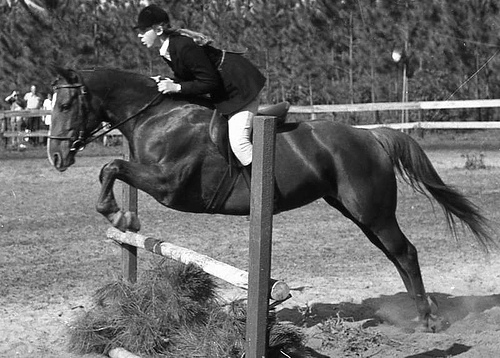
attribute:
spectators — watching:
[6, 86, 60, 116]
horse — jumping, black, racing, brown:
[39, 62, 496, 334]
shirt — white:
[25, 92, 44, 111]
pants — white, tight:
[228, 96, 261, 168]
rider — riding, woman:
[136, 6, 268, 183]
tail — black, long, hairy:
[369, 125, 500, 258]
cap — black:
[132, 5, 172, 33]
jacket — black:
[159, 32, 265, 118]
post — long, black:
[244, 115, 279, 357]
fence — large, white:
[285, 98, 498, 132]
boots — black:
[239, 161, 278, 223]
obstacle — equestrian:
[104, 114, 280, 357]